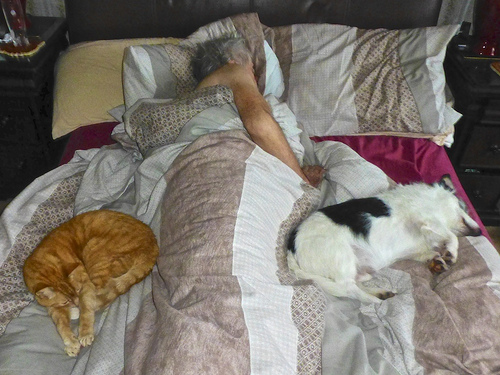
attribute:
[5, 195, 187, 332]
cat — sleeping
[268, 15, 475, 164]
pillow case — patterened, striped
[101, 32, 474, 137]
pillow case — light tan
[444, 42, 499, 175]
end table — black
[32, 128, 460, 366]
bedsheet — red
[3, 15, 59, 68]
nightstand — dark wood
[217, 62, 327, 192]
arm — hairy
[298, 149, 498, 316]
dog — black, white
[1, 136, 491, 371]
sheet — red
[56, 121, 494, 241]
bed sheet — burgandy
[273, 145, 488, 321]
dog — sleeping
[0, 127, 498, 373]
bed spread — white, grey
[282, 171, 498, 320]
paw — light pad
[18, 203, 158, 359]
cat — orange, sleeping, brown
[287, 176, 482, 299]
dog — black, white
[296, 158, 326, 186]
hand — hairy